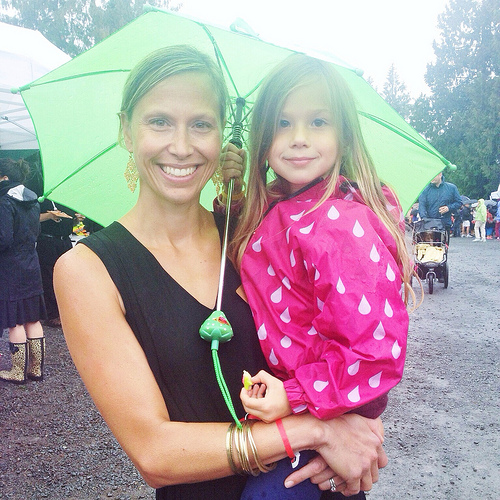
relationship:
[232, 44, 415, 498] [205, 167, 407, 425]
girl wearing coat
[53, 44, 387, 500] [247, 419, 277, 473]
girl wearing bangles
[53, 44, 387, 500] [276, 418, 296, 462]
girl wearing band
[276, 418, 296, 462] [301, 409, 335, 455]
band on wrist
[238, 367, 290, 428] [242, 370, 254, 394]
hand holding food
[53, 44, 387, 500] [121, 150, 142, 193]
girl wearing gold earrings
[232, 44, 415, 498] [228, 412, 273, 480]
girl wearing bangles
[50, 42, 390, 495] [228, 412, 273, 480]
girl wearing bangles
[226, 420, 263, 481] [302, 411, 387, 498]
bangles to hand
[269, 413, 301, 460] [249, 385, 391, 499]
band to hand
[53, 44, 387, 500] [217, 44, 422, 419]
girl holding child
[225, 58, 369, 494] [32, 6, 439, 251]
child holding umbrella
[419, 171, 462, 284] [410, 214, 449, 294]
man pushing baby carriage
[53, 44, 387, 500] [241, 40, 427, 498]
girl holding girl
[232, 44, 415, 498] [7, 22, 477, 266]
girl holding umbrella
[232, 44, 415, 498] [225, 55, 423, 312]
girl with hair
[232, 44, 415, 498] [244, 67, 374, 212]
girl with hair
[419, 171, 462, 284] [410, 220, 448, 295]
man pushing a baby carriage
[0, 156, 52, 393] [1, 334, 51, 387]
woman wearing boots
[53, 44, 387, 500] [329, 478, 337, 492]
girl wearing ring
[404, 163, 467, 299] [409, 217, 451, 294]
man pushing a stroller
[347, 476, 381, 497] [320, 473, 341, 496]
ring to finger